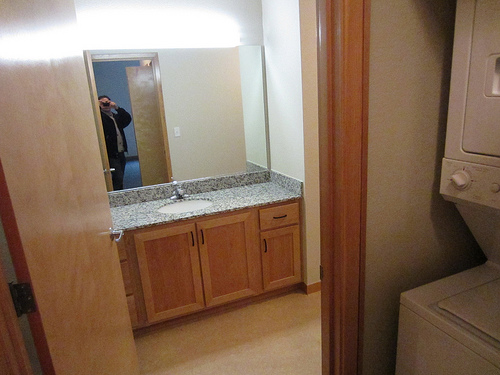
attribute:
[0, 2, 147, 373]
door — open, wooden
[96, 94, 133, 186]
man — light skinned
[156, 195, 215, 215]
sink — clean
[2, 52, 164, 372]
door — wooden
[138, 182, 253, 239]
sink — white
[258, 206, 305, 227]
drawers — closed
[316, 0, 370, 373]
frame — wooden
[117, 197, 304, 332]
cabinets — light wood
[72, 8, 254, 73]
light — bright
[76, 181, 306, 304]
drawers — wooden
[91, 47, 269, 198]
mirror — large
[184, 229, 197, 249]
handle — black, metal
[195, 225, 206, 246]
handle — black, metal